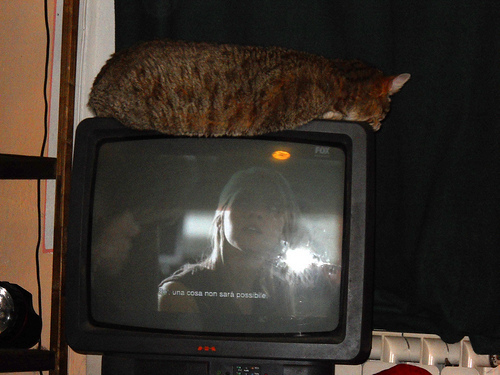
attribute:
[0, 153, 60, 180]
shelf — small, black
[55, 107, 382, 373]
tv set — black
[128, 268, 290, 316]
subtitles — spanish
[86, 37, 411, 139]
cat — gray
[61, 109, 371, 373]
television — old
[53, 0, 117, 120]
window trim — white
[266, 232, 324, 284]
flash — camera